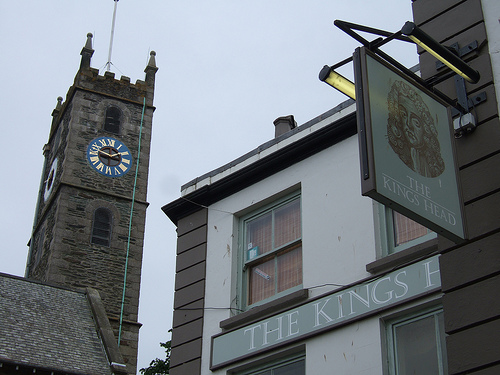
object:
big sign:
[353, 45, 470, 245]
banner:
[210, 250, 440, 369]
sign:
[353, 45, 470, 245]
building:
[158, 6, 495, 374]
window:
[224, 188, 310, 316]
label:
[245, 246, 261, 263]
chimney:
[271, 114, 297, 138]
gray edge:
[179, 61, 421, 198]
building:
[2, 34, 158, 373]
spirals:
[71, 1, 161, 83]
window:
[102, 100, 122, 136]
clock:
[83, 135, 134, 178]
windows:
[226, 180, 450, 375]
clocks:
[42, 135, 132, 204]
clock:
[43, 158, 59, 201]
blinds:
[246, 201, 300, 304]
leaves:
[139, 328, 172, 375]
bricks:
[71, 248, 141, 303]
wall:
[157, 63, 498, 373]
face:
[396, 95, 423, 147]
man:
[385, 82, 445, 176]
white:
[203, 129, 388, 375]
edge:
[157, 180, 189, 373]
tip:
[160, 194, 179, 227]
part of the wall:
[155, 81, 496, 366]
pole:
[102, 1, 125, 77]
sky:
[156, 5, 327, 123]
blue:
[168, 7, 308, 106]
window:
[377, 291, 448, 375]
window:
[375, 201, 438, 262]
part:
[226, 326, 279, 360]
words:
[242, 260, 446, 350]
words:
[380, 171, 459, 227]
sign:
[210, 250, 440, 369]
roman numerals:
[89, 137, 139, 188]